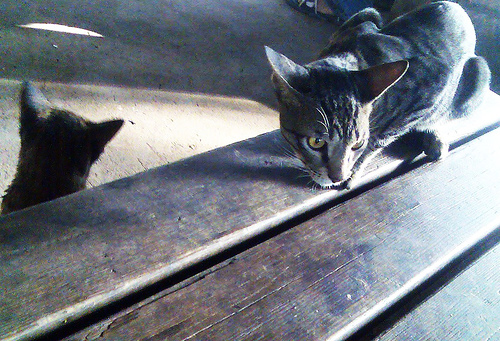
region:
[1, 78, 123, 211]
The back of a cat's head.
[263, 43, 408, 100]
Slanted ears on a cat looking to the right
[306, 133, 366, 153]
Yellow eyes of a cat.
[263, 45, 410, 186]
Head and ears of a cat with yellow eyes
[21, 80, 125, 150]
Ears of a cat that is not facing the camera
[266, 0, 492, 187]
Cat up on a wood table.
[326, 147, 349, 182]
A nose of a cat with yellow eyes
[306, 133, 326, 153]
A cat's right side yellow eye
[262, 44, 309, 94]
The right ear of a cat with yellow eyes on a table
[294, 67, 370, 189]
Head of a yellow eyed cat.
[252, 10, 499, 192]
cat laying on a bench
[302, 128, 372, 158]
two bright green eyes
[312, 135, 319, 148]
black slit on the eyeball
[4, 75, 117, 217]
cat sitting on the ground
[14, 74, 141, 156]
two pointy ears sticking out of either side of the head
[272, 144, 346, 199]
whiskers coming off the face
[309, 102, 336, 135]
long white hairs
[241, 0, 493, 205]
gray cat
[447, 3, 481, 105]
light shining on the cat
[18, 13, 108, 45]
light shining on the ground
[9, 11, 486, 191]
two gray colored cats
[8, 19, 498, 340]
cat sitting on table top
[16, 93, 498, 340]
wood slats of table top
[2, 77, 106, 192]
cat looking into distance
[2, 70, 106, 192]
cat with back to camera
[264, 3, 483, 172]
cat crouched on table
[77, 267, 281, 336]
crack in wood slate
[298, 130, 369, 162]
eyes of gray cat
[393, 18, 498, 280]
sunlight shining on cat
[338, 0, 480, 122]
body of crouching cat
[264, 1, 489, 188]
crouching cat on a bench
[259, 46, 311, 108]
right furry ear of crouching cat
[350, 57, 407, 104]
furry left ear of crouching cat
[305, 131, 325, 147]
little black and yellow right eye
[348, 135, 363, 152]
little white and yellow left eye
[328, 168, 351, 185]
small pinky nose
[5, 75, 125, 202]
cat standing in the ground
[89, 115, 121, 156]
small furry right ear of cat in the floor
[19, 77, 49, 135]
small furry left ear of cat in the floor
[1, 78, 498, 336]
brown wooden bench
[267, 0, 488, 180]
this is a cat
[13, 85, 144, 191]
this is a cat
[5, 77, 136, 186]
the head of a cat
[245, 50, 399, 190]
the head of a cat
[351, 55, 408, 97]
the ear of a cat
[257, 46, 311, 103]
the ear of a cat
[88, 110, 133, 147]
the ear of a cat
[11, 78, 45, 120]
the ear of a cat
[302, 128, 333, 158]
the eye of a cat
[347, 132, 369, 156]
the eye of a cat